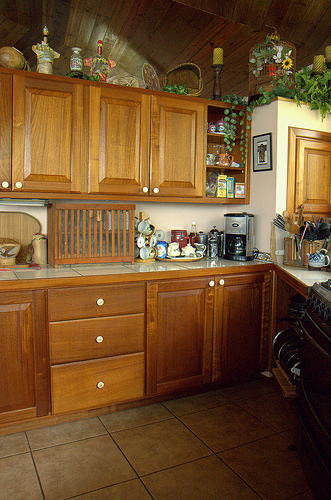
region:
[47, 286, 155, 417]
row of three drawers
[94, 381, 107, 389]
small white knob on the drawer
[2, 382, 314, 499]
tile on the floor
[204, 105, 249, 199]
various food items on the shelves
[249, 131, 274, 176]
decoration on the wall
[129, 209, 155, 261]
mugs hanging on a mug holder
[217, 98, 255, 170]
leaves hanging down in front of the cabinet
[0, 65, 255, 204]
cabinets hanging on the wall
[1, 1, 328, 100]
wood paneling on the ceiling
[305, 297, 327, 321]
a row of black knobs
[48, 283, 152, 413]
the drawers are closed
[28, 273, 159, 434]
the drawers are closed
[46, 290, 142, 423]
the drawers are closed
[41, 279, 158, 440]
the drawers are closed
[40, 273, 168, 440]
the drawers are closed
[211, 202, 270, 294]
coffeemaker on the countertop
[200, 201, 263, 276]
coffeemaker on the countertop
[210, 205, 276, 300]
coffeemaker on the countertop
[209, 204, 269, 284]
coffeemaker on the countertop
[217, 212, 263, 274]
coffeemaker on the countertop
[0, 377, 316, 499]
the tiles on the floor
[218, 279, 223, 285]
the knob on the cabinet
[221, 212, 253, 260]
the coffee maker on the counter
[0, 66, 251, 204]
the wooden top cabinets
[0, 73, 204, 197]
the doors on the cabinets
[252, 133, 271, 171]
the picture on the wall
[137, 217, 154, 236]
the cup hanging on the rack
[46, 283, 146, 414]
the drawers under the counter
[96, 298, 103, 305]
the knob on the drawer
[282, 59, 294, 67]
the flower is yellow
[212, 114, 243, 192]
the cabinet has no door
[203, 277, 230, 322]
the doors are closed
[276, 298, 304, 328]
the pots are on the top shelf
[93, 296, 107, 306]
the knob is white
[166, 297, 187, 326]
the cabinet is brown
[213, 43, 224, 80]
the candle is on the holder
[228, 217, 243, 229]
the coffee pot is silver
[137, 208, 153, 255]
the cups are hanging on the holder